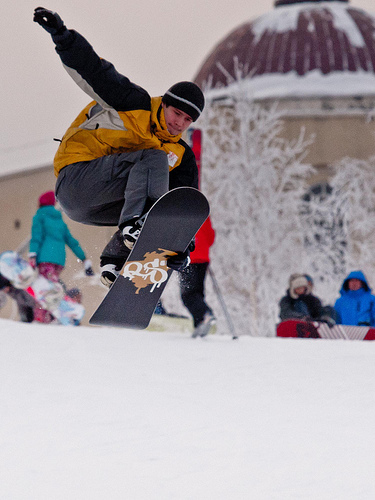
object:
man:
[32, 6, 204, 290]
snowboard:
[89, 181, 218, 330]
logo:
[119, 245, 177, 295]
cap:
[159, 78, 206, 123]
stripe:
[165, 89, 206, 118]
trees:
[198, 63, 314, 339]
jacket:
[50, 29, 202, 185]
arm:
[53, 30, 151, 113]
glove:
[31, 5, 68, 37]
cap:
[38, 189, 56, 207]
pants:
[52, 146, 171, 228]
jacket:
[27, 204, 85, 264]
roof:
[191, 0, 375, 87]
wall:
[281, 115, 375, 190]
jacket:
[335, 265, 375, 326]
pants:
[178, 261, 218, 326]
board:
[276, 320, 372, 341]